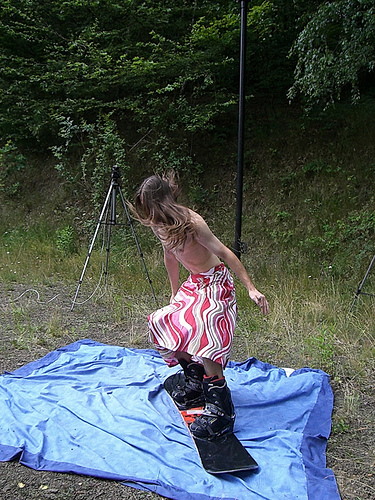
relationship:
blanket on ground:
[8, 320, 339, 497] [267, 331, 370, 395]